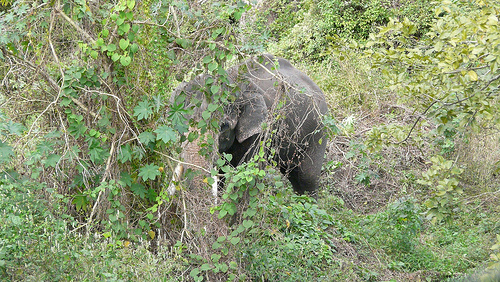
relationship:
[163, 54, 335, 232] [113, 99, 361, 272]
elephant an elephant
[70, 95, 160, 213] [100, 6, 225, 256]
leaves are attached to branch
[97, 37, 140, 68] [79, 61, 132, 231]
leaves are on branch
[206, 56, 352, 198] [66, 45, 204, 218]
elephant behind bushes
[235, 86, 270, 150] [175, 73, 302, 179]
ear on elephant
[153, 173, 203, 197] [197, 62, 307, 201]
tusk on elephant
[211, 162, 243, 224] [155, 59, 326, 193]
tusk on elephant